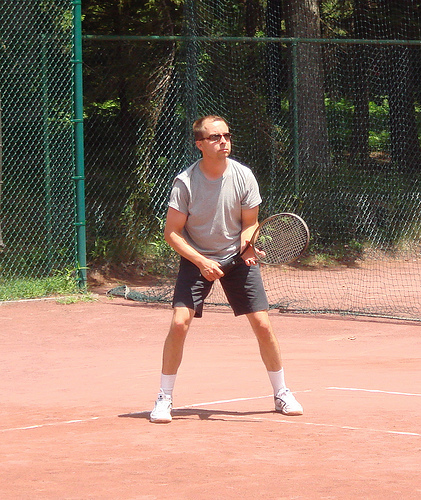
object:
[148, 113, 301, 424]
man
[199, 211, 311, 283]
racket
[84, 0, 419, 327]
fence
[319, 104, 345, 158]
ground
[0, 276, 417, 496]
court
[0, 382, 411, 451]
lines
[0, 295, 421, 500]
tennis court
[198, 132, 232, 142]
sunglasses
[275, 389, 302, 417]
shoe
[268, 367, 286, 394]
high-top sock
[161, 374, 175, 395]
high-top sock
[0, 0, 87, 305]
fence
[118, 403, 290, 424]
shadow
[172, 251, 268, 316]
black shorts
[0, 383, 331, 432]
chalk mark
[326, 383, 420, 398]
chalk mark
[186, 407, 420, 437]
chalk mark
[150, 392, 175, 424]
shoe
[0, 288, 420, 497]
field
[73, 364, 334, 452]
ground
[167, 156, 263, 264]
shirt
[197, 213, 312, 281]
tennis